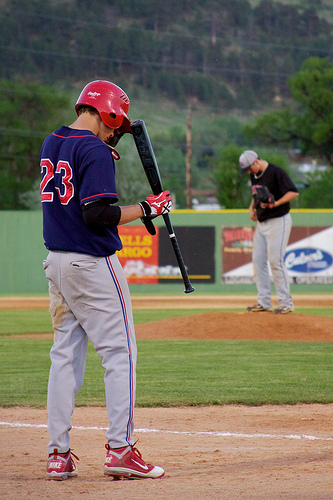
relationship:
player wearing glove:
[28, 74, 178, 485] [134, 187, 174, 235]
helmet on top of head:
[77, 82, 131, 126] [72, 79, 129, 139]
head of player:
[72, 79, 129, 139] [39, 79, 172, 478]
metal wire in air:
[3, 42, 296, 82] [0, 0, 331, 207]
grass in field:
[0, 306, 333, 408] [5, 342, 37, 385]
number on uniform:
[38, 157, 73, 204] [37, 125, 125, 256]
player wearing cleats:
[39, 79, 172, 478] [101, 443, 149, 473]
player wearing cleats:
[39, 79, 172, 478] [44, 457, 68, 469]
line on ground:
[1, 421, 332, 441] [1, 403, 332, 498]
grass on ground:
[2, 310, 332, 403] [1, 298, 332, 499]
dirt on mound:
[211, 319, 262, 340] [203, 315, 322, 335]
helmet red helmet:
[75, 78, 131, 147] [73, 79, 134, 136]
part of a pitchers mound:
[116, 291, 234, 366] [140, 310, 332, 338]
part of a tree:
[186, 179, 228, 215] [241, 54, 331, 168]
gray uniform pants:
[69, 311, 202, 473] [27, 255, 170, 450]